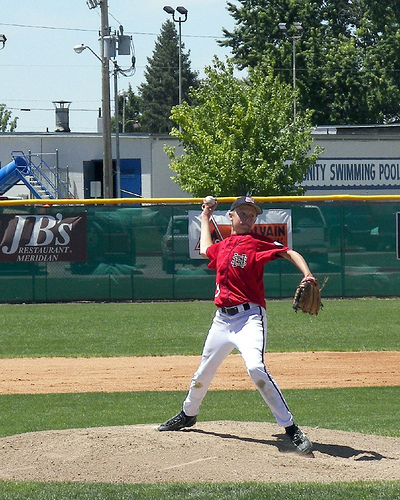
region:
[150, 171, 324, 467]
Young boy playing baseball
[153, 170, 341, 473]
Young boy about to throw a baseball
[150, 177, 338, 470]
Young boy holding a baseball and mitt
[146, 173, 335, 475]
Young boy wearing a red baseball jersey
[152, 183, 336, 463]
Young boy wearing a black baseball cap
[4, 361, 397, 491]
Pitchers mound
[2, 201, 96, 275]
Advertiser's sign on the fencing of the ball park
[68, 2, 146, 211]
Power pole and street light in the parking lot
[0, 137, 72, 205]
Blue waterslide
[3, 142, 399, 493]
Young boy pitching a baseball at a baseball game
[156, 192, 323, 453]
boy in baseball uniform throwing a ball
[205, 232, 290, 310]
baseball uniform red shirt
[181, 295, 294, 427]
baseball uniform white pants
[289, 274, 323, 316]
tan baseball glove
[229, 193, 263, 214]
dark baseball uniform cap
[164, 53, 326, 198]
small green tree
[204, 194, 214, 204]
white baseball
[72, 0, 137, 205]
brown utility pole with light attatched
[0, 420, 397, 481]
pitcher's mound of light colored sand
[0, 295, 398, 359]
green grass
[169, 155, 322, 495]
a boy throwing a baseball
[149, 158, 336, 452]
a boy wearing a baseball uniform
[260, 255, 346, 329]
a glove on a hand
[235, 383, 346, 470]
a cleat in the sand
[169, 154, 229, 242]
a a baseball in a hand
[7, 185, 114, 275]
a banner on a fence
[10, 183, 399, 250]
a pad on a fence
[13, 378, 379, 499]
a pitcher's mound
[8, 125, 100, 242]
stairs to a slide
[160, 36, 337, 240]
a tree behind a fence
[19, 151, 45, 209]
a set of blue stairs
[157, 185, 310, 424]
a young boy throwing a baseball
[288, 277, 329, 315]
a baseball glove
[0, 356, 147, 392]
a patch of dirt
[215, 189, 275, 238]
a young boy wearing a ball cap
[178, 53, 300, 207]
a tree with green leaves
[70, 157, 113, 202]
a open door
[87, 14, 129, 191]
a electrical pole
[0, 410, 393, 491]
a mound of dirt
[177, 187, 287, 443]
a young boy wearing a baseball uniform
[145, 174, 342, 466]
Baseball player with ball on right hand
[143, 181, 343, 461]
Baseball player has white pants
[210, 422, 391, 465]
Shadow of player cast on the ground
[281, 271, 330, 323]
Hat on hand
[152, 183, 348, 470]
Boy wears a glove in his left hand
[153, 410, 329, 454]
Shoe is grey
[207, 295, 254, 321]
Belt is brown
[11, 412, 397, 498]
Soil in middle of green grass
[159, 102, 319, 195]
Tree on the road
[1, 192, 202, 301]
Baseball field is fenced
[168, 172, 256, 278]
boy holding base ball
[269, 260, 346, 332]
boy wearing baseball mit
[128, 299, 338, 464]
boy wearing white pants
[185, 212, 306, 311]
boy wearing red shirt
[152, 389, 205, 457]
boy wearing black shoes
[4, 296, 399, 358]
green grass patch on baseball field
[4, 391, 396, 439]
green grass patch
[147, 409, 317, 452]
black baseball cleats on boy